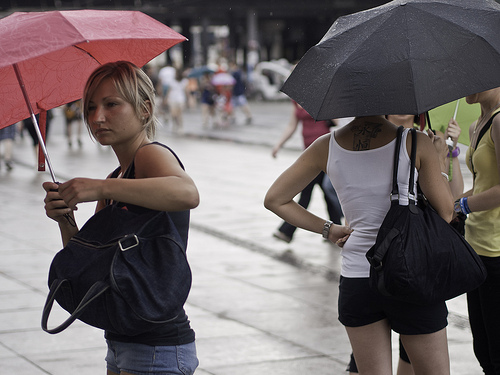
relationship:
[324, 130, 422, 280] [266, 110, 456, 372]
white tank on woman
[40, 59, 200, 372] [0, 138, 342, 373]
person on pavement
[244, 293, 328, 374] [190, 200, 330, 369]
line in pavement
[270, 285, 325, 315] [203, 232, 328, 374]
line in pavement